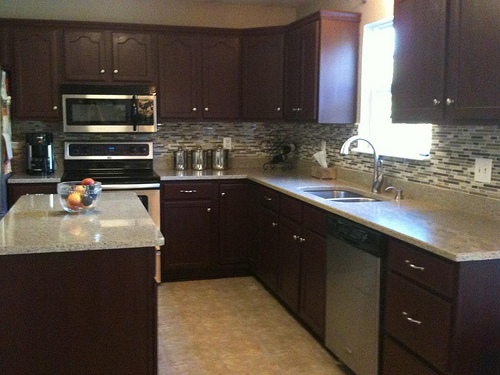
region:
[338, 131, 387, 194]
chrome colored faucet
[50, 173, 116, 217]
bowl of fruit on counter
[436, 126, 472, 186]
brown,white and tan tiles on wall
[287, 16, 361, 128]
brown cabinet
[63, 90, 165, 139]
microwave with black and chrome color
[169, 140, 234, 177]
three chrome canisters on the counter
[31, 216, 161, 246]
white,tan and brown counter top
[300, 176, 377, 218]
sink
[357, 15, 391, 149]
window with bright light shining through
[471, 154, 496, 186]
white light switch on the wall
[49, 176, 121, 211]
a glass bowl of fruit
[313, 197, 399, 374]
a stainless steal dishwasher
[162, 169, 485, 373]
brown cabinets in the kitchen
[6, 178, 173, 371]
an island with marble top in kitchen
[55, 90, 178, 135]
a microwave above the stove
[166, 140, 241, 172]
three silver canisters aligned on the counter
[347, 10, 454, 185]
a window with the sun shining threw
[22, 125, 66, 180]
a black and silver coffee pot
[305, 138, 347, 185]
a box of kleenix on the kitchen counter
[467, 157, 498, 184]
two light switches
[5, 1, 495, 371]
a large kitchen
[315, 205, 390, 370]
a silver and black dishwasher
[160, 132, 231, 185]
metal canisters on a counter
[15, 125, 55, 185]
a black and silver coffeemaker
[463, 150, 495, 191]
light switches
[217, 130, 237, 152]
a power outlet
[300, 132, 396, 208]
a sink with a tall curved faucet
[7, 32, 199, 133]
a black and silver microwave set amidst dark cabinets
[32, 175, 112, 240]
a bowl of fruit on a counter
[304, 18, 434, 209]
a window above the sink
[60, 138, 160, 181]
tope of the stove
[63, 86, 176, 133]
microwave mounted above the stove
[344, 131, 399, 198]
faucet at kitchen sink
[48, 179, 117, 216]
fruit bowl on the cupboard in the middle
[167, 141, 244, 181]
three metal storage units on the counter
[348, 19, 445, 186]
window between the two cupboards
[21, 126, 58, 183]
coffee maker next to the stove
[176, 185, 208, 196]
drawer handle to the right of the stove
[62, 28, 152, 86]
two cupboard doors above the microwave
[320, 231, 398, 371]
dishwasher built into the cupboard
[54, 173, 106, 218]
a glass fruit bowl on the table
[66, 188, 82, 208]
an orange in the bowl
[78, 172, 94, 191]
a red apple in the bowl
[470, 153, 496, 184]
a white light switch on the wall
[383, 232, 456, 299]
a brown wooden cabinet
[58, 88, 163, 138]
a microwave over the stove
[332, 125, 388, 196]
a gray metal faucet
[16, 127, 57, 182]
a black coffee maker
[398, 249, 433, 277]
a metal handle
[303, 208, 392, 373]
a dish washer